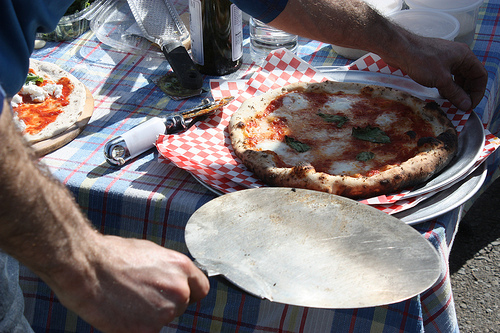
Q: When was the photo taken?
A: Daytime.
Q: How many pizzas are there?
A: Two.